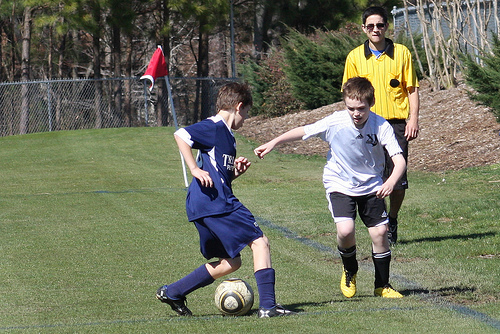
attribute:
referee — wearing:
[338, 3, 423, 244]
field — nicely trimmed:
[14, 153, 136, 275]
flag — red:
[140, 40, 169, 89]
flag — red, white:
[138, 43, 169, 90]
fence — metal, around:
[12, 77, 119, 138]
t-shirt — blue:
[367, 47, 385, 55]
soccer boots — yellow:
[338, 266, 403, 298]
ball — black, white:
[213, 275, 255, 317]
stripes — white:
[370, 251, 393, 261]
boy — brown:
[252, 67, 426, 303]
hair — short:
[337, 68, 379, 102]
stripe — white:
[337, 248, 357, 258]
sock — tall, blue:
[162, 260, 215, 300]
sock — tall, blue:
[252, 267, 277, 309]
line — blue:
[254, 213, 499, 330]